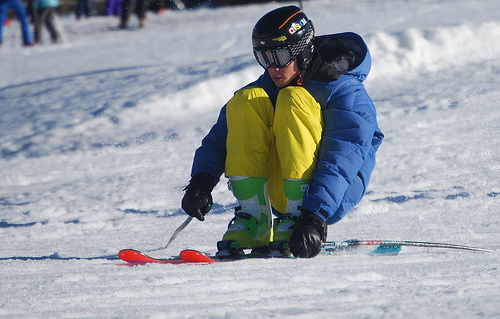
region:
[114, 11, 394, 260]
person crouched on skis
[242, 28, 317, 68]
black and white ski goggles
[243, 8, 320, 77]
black helmet with red stripe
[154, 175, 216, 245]
right hand holding ski pole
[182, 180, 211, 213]
black glove on right hand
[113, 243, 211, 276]
reddish orange front of skis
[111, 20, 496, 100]
ridge of white snow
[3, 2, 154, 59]
legs of people walking in snow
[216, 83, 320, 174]
baggy yellow snow pants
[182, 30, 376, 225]
blue jacket with hood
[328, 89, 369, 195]
man wearing blue color jacket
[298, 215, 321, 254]
man wearing black color gloves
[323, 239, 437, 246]
man holding skiing rod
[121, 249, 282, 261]
man resting on skiing board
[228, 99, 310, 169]
man wearing yellow color pants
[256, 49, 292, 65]
man wearing skiing glasses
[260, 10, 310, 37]
man wearing black skiing helmet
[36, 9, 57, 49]
man wearing black color pants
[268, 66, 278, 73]
nose of the man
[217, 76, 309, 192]
knees up to chest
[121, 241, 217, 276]
bottom of skis are orange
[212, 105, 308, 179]
pants on girl are yellow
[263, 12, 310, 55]
black helmet on the head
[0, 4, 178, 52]
people in back on snow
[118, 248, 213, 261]
the skiis are orange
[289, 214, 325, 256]
the glove is black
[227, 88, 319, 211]
the pants are yellow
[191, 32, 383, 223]
the jacket is blue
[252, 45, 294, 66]
man is wearing goggles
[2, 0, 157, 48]
people in the back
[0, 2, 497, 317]
snow all over ground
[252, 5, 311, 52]
man is wearing helmet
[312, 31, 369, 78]
hood of the jacket